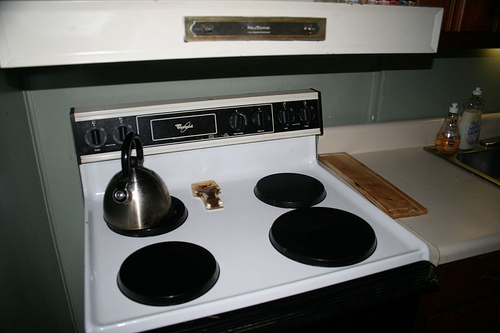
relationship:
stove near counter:
[75, 98, 326, 292] [359, 154, 464, 222]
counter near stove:
[359, 154, 464, 222] [75, 98, 326, 292]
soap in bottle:
[437, 129, 460, 150] [441, 101, 460, 156]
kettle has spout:
[104, 149, 163, 234] [117, 185, 130, 205]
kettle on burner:
[104, 149, 163, 234] [123, 241, 207, 296]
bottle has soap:
[441, 101, 460, 156] [437, 129, 460, 150]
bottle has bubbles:
[441, 101, 460, 156] [441, 134, 457, 151]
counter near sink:
[359, 154, 464, 222] [466, 150, 500, 170]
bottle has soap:
[471, 87, 480, 148] [437, 129, 460, 150]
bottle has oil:
[441, 101, 460, 156] [443, 133, 460, 153]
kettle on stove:
[104, 149, 163, 234] [75, 98, 326, 292]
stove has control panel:
[75, 98, 326, 292] [77, 113, 324, 145]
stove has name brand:
[75, 98, 326, 292] [170, 122, 206, 139]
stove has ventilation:
[75, 98, 326, 292] [14, 1, 443, 74]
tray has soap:
[423, 144, 459, 159] [437, 129, 460, 150]